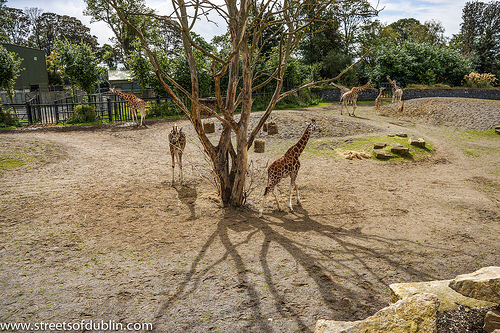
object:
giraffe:
[167, 122, 188, 187]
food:
[202, 121, 215, 132]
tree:
[83, 1, 378, 206]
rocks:
[406, 134, 427, 147]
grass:
[281, 129, 436, 162]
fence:
[0, 82, 294, 127]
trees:
[443, 1, 500, 81]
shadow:
[152, 212, 499, 333]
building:
[104, 68, 222, 104]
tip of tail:
[262, 186, 270, 197]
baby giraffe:
[372, 84, 389, 111]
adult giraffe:
[338, 81, 375, 118]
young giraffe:
[255, 116, 324, 221]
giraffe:
[109, 85, 147, 126]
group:
[338, 75, 408, 118]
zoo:
[3, 3, 499, 332]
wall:
[310, 86, 500, 103]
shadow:
[173, 179, 201, 224]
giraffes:
[327, 81, 359, 106]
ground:
[1, 97, 500, 331]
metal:
[0, 90, 295, 127]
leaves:
[71, 59, 82, 69]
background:
[0, 0, 500, 88]